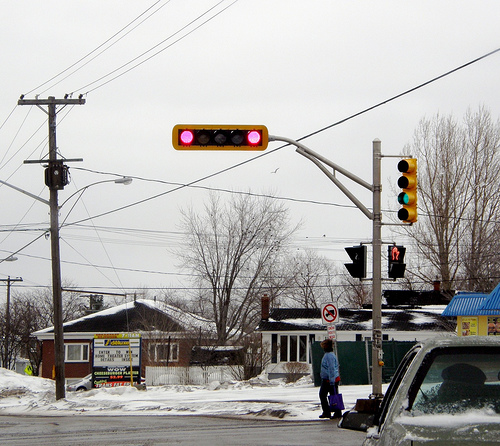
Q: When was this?
A: Daytime.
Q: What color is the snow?
A: White.